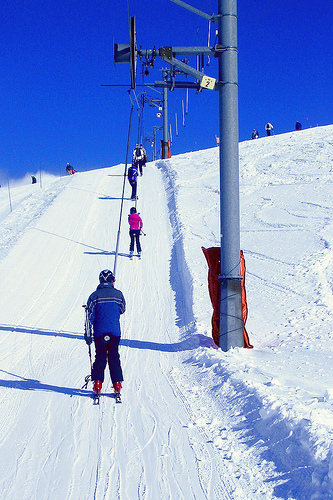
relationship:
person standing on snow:
[128, 197, 161, 263] [18, 152, 258, 365]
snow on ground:
[0, 124, 331, 497] [19, 159, 321, 496]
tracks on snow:
[0, 129, 331, 498] [0, 124, 331, 497]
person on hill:
[125, 162, 143, 200] [78, 149, 219, 474]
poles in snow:
[172, 47, 290, 401] [265, 160, 327, 227]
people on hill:
[238, 118, 324, 141] [5, 133, 331, 187]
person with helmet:
[128, 162, 139, 199] [98, 268, 117, 285]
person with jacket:
[128, 206, 144, 257] [120, 214, 144, 228]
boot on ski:
[91, 380, 101, 394] [93, 393, 98, 404]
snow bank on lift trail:
[138, 147, 331, 497] [0, 158, 329, 496]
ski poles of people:
[82, 299, 94, 386] [83, 270, 126, 396]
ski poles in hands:
[82, 299, 94, 386] [82, 329, 95, 345]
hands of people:
[82, 329, 95, 345] [83, 270, 126, 396]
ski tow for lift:
[104, 69, 172, 133] [113, 89, 154, 285]